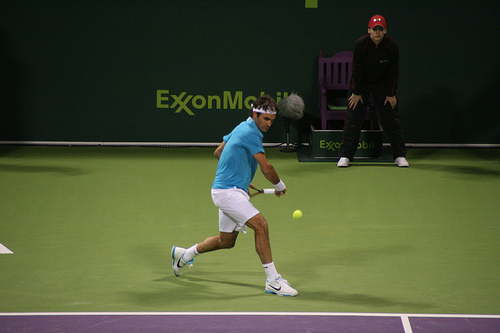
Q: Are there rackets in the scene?
A: Yes, there is a racket.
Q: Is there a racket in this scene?
A: Yes, there is a racket.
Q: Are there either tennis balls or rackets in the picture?
A: Yes, there is a racket.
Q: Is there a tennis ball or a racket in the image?
A: Yes, there is a racket.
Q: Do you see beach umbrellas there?
A: No, there are no beach umbrellas.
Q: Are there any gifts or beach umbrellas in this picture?
A: No, there are no beach umbrellas or gifts.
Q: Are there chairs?
A: Yes, there is a chair.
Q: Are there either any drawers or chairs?
A: Yes, there is a chair.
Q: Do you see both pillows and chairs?
A: No, there is a chair but no pillows.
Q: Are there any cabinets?
A: No, there are no cabinets.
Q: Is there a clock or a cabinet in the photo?
A: No, there are no cabinets or clocks.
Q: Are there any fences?
A: No, there are no fences.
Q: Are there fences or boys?
A: No, there are no fences or boys.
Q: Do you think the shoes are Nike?
A: Yes, the shoes are nike.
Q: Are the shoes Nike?
A: Yes, the shoes are nike.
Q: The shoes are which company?
A: The shoes are nike.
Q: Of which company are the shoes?
A: The shoes are nike.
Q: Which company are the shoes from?
A: The shoes are from nike.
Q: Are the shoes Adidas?
A: No, the shoes are nike.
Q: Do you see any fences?
A: No, there are no fences.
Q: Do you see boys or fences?
A: No, there are no fences or boys.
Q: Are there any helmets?
A: No, there are no helmets.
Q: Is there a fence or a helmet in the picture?
A: No, there are no helmets or fences.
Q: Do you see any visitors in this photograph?
A: No, there are no visitors.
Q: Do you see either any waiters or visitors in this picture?
A: No, there are no visitors or waiters.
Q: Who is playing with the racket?
A: The man is playing with the racket.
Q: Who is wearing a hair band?
A: The man is wearing a hair band.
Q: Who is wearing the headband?
A: The man is wearing a hair band.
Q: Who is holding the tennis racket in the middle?
A: The man is holding the tennis racket.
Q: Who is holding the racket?
A: The man is holding the tennis racket.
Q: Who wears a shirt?
A: The man wears a shirt.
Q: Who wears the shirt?
A: The man wears a shirt.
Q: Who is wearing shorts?
A: The man is wearing shorts.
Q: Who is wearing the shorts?
A: The man is wearing shorts.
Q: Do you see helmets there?
A: No, there are no helmets.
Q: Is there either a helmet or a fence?
A: No, there are no helmets or fences.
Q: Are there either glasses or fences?
A: No, there are no fences or glasses.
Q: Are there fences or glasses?
A: No, there are no fences or glasses.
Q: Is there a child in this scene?
A: No, there are no children.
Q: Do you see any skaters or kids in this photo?
A: No, there are no kids or skaters.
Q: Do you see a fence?
A: No, there are no fences.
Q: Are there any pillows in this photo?
A: No, there are no pillows.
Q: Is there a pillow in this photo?
A: No, there are no pillows.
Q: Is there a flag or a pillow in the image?
A: No, there are no pillows or flags.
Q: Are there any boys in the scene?
A: No, there are no boys.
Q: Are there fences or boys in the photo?
A: No, there are no boys or fences.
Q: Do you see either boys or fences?
A: No, there are no boys or fences.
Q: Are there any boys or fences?
A: No, there are no boys or fences.